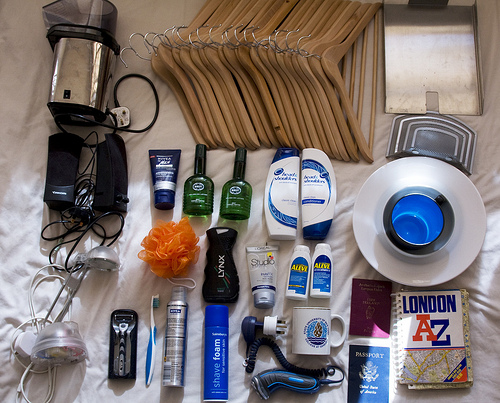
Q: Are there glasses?
A: No, there are no glasses.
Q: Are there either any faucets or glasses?
A: No, there are no glasses or faucets.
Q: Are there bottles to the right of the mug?
A: Yes, there are bottles to the right of the mug.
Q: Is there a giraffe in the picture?
A: No, there are no giraffes.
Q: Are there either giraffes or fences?
A: No, there are no giraffes or fences.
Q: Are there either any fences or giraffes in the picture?
A: No, there are no giraffes or fences.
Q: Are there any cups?
A: Yes, there is a cup.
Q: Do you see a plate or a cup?
A: Yes, there is a cup.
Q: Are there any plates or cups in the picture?
A: Yes, there is a cup.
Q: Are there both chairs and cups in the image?
A: No, there is a cup but no chairs.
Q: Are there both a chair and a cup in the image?
A: No, there is a cup but no chairs.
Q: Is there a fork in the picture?
A: No, there are no forks.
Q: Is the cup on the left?
A: No, the cup is on the right of the image.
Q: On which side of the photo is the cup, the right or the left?
A: The cup is on the right of the image.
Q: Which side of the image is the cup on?
A: The cup is on the right of the image.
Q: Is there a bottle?
A: Yes, there is a bottle.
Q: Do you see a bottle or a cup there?
A: Yes, there is a bottle.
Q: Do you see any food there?
A: No, there is no food.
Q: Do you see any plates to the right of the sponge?
A: No, there is a bottle to the right of the sponge.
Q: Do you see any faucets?
A: No, there are no faucets.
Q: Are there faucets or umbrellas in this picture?
A: No, there are no faucets or umbrellas.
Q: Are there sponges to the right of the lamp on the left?
A: Yes, there is a sponge to the right of the lamp.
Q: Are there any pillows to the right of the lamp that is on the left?
A: No, there is a sponge to the right of the lamp.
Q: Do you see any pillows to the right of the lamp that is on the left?
A: No, there is a sponge to the right of the lamp.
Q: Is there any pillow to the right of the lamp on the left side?
A: No, there is a sponge to the right of the lamp.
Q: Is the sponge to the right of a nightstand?
A: No, the sponge is to the right of the lamp.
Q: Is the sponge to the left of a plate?
A: No, the sponge is to the left of the bottle.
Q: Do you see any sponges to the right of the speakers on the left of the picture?
A: Yes, there is a sponge to the right of the speakers.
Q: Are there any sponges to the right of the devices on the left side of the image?
A: Yes, there is a sponge to the right of the speakers.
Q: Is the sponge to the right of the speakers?
A: Yes, the sponge is to the right of the speakers.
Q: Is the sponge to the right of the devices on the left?
A: Yes, the sponge is to the right of the speakers.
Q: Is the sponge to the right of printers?
A: No, the sponge is to the right of the speakers.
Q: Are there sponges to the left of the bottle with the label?
A: Yes, there is a sponge to the left of the bottle.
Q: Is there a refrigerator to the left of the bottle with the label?
A: No, there is a sponge to the left of the bottle.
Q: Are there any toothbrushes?
A: Yes, there is a toothbrush.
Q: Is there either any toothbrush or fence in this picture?
A: Yes, there is a toothbrush.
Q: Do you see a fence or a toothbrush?
A: Yes, there is a toothbrush.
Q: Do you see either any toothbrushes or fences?
A: Yes, there is a toothbrush.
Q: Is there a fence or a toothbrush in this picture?
A: Yes, there is a toothbrush.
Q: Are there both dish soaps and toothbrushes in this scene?
A: No, there is a toothbrush but no dish soaps.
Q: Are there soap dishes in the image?
A: No, there are no soap dishes.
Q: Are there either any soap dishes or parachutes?
A: No, there are no soap dishes or parachutes.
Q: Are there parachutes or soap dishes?
A: No, there are no soap dishes or parachutes.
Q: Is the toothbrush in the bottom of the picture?
A: Yes, the toothbrush is in the bottom of the image.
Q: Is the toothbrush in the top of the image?
A: No, the toothbrush is in the bottom of the image.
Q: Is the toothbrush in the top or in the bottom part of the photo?
A: The toothbrush is in the bottom of the image.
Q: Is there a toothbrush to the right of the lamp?
A: Yes, there is a toothbrush to the right of the lamp.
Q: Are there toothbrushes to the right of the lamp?
A: Yes, there is a toothbrush to the right of the lamp.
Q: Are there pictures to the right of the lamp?
A: No, there is a toothbrush to the right of the lamp.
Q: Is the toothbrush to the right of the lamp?
A: Yes, the toothbrush is to the right of the lamp.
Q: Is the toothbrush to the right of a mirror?
A: No, the toothbrush is to the right of the lamp.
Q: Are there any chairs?
A: No, there are no chairs.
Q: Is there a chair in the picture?
A: No, there are no chairs.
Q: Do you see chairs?
A: No, there are no chairs.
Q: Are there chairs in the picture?
A: No, there are no chairs.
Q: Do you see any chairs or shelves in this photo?
A: No, there are no chairs or shelves.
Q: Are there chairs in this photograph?
A: No, there are no chairs.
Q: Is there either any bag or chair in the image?
A: No, there are no chairs or bags.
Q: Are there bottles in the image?
A: Yes, there is a bottle.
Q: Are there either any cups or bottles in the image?
A: Yes, there is a bottle.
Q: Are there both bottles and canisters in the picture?
A: No, there is a bottle but no canisters.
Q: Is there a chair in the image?
A: No, there are no chairs.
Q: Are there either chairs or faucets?
A: No, there are no chairs or faucets.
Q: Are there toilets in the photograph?
A: No, there are no toilets.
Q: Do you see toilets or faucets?
A: No, there are no toilets or faucets.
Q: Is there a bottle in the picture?
A: Yes, there is a bottle.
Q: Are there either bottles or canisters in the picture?
A: Yes, there is a bottle.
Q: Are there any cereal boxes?
A: No, there are no cereal boxes.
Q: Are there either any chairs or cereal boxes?
A: No, there are no cereal boxes or chairs.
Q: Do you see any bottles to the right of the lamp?
A: Yes, there is a bottle to the right of the lamp.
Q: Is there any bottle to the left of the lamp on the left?
A: No, the bottle is to the right of the lamp.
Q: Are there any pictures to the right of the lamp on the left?
A: No, there is a bottle to the right of the lamp.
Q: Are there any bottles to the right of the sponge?
A: Yes, there is a bottle to the right of the sponge.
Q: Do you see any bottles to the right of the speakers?
A: Yes, there is a bottle to the right of the speakers.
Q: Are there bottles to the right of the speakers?
A: Yes, there is a bottle to the right of the speakers.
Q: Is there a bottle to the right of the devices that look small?
A: Yes, there is a bottle to the right of the speakers.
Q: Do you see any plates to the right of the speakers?
A: No, there is a bottle to the right of the speakers.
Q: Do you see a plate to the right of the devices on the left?
A: No, there is a bottle to the right of the speakers.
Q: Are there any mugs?
A: Yes, there is a mug.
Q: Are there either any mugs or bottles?
A: Yes, there is a mug.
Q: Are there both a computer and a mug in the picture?
A: No, there is a mug but no computers.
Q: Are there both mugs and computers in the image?
A: No, there is a mug but no computers.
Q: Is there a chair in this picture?
A: No, there are no chairs.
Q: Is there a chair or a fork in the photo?
A: No, there are no chairs or forks.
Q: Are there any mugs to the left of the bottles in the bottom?
A: Yes, there is a mug to the left of the bottles.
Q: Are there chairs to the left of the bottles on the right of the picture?
A: No, there is a mug to the left of the bottles.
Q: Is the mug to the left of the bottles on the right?
A: Yes, the mug is to the left of the bottles.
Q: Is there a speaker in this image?
A: Yes, there are speakers.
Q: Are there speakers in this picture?
A: Yes, there are speakers.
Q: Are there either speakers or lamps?
A: Yes, there are speakers.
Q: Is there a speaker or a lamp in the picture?
A: Yes, there are speakers.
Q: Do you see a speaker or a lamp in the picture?
A: Yes, there are speakers.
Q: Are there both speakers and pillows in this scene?
A: No, there are speakers but no pillows.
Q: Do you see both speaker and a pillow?
A: No, there are speakers but no pillows.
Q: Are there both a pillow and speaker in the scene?
A: No, there are speakers but no pillows.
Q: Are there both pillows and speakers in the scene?
A: No, there are speakers but no pillows.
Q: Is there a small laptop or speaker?
A: Yes, there are small speakers.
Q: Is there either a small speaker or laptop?
A: Yes, there are small speakers.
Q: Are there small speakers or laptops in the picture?
A: Yes, there are small speakers.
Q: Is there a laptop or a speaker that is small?
A: Yes, the speakers are small.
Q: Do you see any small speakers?
A: Yes, there are small speakers.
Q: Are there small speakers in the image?
A: Yes, there are small speakers.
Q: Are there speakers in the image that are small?
A: Yes, there are speakers that are small.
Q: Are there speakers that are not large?
A: Yes, there are small speakers.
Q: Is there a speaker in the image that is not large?
A: Yes, there are small speakers.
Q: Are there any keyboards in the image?
A: No, there are no keyboards.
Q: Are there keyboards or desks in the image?
A: No, there are no keyboards or desks.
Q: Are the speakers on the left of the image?
A: Yes, the speakers are on the left of the image.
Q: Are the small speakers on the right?
A: No, the speakers are on the left of the image.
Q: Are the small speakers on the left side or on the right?
A: The speakers are on the left of the image.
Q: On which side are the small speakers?
A: The speakers are on the left of the image.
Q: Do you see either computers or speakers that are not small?
A: No, there are speakers but they are small.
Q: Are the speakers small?
A: Yes, the speakers are small.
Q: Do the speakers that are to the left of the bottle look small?
A: Yes, the speakers are small.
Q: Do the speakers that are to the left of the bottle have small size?
A: Yes, the speakers are small.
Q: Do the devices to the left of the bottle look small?
A: Yes, the speakers are small.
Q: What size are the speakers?
A: The speakers are small.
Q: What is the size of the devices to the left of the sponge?
A: The speakers are small.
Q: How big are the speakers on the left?
A: The speakers are small.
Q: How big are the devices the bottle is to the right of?
A: The speakers are small.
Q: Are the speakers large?
A: No, the speakers are small.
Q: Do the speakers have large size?
A: No, the speakers are small.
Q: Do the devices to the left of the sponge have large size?
A: No, the speakers are small.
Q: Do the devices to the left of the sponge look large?
A: No, the speakers are small.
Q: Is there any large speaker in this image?
A: No, there are speakers but they are small.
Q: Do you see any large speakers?
A: No, there are speakers but they are small.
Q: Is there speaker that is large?
A: No, there are speakers but they are small.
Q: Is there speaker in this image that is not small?
A: No, there are speakers but they are small.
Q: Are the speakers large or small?
A: The speakers are small.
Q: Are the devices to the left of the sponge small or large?
A: The speakers are small.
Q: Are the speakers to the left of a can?
A: No, the speakers are to the left of the bottle.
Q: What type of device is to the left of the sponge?
A: The devices are speakers.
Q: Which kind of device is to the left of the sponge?
A: The devices are speakers.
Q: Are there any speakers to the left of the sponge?
A: Yes, there are speakers to the left of the sponge.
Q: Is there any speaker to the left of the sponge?
A: Yes, there are speakers to the left of the sponge.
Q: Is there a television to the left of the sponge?
A: No, there are speakers to the left of the sponge.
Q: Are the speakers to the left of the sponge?
A: Yes, the speakers are to the left of the sponge.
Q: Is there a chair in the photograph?
A: No, there are no chairs.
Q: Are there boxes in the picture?
A: No, there are no boxes.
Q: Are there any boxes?
A: No, there are no boxes.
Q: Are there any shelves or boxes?
A: No, there are no boxes or shelves.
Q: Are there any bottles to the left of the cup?
A: Yes, there are bottles to the left of the cup.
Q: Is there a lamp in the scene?
A: Yes, there is a lamp.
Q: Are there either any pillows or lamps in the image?
A: Yes, there is a lamp.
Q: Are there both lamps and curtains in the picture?
A: No, there is a lamp but no curtains.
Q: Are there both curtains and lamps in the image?
A: No, there is a lamp but no curtains.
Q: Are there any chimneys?
A: No, there are no chimneys.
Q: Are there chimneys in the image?
A: No, there are no chimneys.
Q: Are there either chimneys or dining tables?
A: No, there are no chimneys or dining tables.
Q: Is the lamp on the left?
A: Yes, the lamp is on the left of the image.